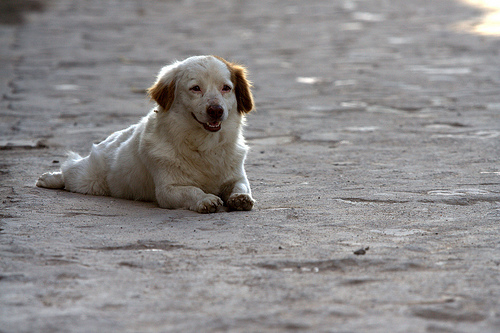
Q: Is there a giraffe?
A: No, there are no giraffes.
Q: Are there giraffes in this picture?
A: No, there are no giraffes.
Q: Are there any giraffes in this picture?
A: No, there are no giraffes.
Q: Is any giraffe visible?
A: No, there are no giraffes.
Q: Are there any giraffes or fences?
A: No, there are no giraffes or fences.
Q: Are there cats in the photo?
A: No, there are no cats.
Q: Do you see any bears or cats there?
A: No, there are no cats or bears.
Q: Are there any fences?
A: No, there are no fences.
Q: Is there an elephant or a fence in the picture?
A: No, there are no fences or elephants.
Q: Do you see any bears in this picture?
A: No, there are no bears.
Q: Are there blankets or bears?
A: No, there are no bears or blankets.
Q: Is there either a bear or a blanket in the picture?
A: No, there are no bears or blankets.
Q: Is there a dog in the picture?
A: Yes, there is a dog.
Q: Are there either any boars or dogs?
A: Yes, there is a dog.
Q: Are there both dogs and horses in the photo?
A: No, there is a dog but no horses.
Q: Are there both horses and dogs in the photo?
A: No, there is a dog but no horses.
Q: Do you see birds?
A: No, there are no birds.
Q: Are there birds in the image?
A: No, there are no birds.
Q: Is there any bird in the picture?
A: No, there are no birds.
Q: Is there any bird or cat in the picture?
A: No, there are no birds or cats.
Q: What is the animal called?
A: The animal is a dog.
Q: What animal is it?
A: The animal is a dog.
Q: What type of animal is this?
A: This is a dog.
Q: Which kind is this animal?
A: This is a dog.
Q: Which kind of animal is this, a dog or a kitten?
A: This is a dog.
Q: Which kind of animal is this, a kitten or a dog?
A: This is a dog.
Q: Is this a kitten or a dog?
A: This is a dog.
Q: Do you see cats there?
A: No, there are no cats.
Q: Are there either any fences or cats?
A: No, there are no cats or fences.